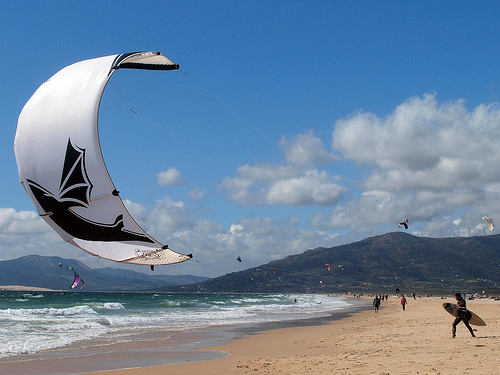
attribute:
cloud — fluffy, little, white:
[245, 94, 498, 233]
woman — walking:
[402, 294, 410, 309]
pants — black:
[399, 301, 405, 306]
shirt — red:
[399, 298, 405, 300]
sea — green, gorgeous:
[7, 281, 350, 370]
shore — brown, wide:
[117, 287, 497, 374]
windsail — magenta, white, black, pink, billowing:
[62, 264, 85, 294]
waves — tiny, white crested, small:
[7, 304, 143, 351]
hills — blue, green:
[3, 230, 499, 297]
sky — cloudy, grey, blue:
[3, 0, 500, 250]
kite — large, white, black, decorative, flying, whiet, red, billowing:
[14, 52, 192, 270]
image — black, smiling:
[23, 143, 156, 250]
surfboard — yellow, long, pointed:
[440, 301, 487, 329]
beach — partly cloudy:
[4, 1, 495, 374]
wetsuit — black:
[453, 301, 473, 320]